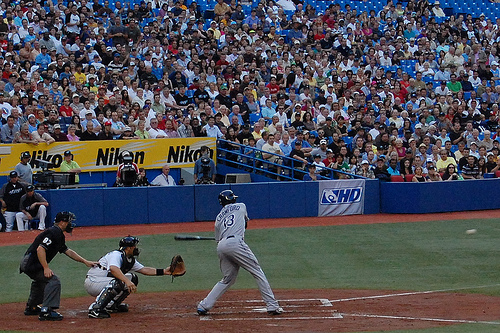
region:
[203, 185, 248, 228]
the head of a man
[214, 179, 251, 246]
the back of a man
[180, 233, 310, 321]
the legs of a man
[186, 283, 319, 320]
the feet of a man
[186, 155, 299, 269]
a man holding a bat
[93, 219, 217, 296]
a man wearing a baseball glove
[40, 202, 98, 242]
a man wearing a face mask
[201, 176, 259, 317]
a man wearing a uniform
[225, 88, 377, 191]
people in the stands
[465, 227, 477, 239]
a white baseball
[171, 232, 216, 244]
a long black baseball bat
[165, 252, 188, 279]
a large brown glove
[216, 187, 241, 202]
a black helmet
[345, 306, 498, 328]
a long white line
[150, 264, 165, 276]
a black wristband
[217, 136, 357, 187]
a long blue rail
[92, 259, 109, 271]
part of a man's black belt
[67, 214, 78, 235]
a black face mask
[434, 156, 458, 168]
a man's yellow shirt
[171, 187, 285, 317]
Baseball player playing baseball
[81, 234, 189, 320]
Catcher playing baseball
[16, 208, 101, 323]
Baseball referee playing baseball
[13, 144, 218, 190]
Camera men recording a baseball game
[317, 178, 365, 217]
Advertisement sign on a baseball field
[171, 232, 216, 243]
Black baseball bat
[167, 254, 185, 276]
Baseball catching mitt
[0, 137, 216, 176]
Yellow advertisement sign for Nikon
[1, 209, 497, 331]
Baseball playing field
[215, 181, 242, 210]
a man wearing a helmet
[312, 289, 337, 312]
a white line on the ground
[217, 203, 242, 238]
a number on the back of a shirt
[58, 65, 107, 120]
people watching a baseball game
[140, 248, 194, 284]
a man with a brown baseball glove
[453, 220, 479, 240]
a ball flying in the air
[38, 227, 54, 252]
numbers on the sleeve of the shirt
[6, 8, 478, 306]
Major league baseball game being played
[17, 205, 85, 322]
umpire in protective gear observing the game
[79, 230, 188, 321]
catcher with his arm extended preparing to catch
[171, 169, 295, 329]
batter in position to play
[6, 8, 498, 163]
large group of spectators in the stadium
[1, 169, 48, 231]
coaches observing from the side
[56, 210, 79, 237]
black face mask on the umpires face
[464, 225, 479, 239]
white baseball sailing through the air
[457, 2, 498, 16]
empty blue stadium seats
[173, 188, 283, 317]
baseball player ready to hit the ball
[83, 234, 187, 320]
baseball catcher waiting for the ball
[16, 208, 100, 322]
umpire watches pitch closely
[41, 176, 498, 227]
blue padding at the fences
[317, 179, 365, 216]
blue and white advertising on fence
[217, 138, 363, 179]
blue metal railing around where spectator's are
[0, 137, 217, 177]
yellow black and white Nikon advertisement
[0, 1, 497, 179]
spectators at the ball game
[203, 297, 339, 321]
home plate marked off in white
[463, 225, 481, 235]
ball moving along at the batter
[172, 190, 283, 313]
a baseball player at bat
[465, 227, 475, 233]
a white baseball in mid flight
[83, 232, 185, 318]
a baseball catcher crouching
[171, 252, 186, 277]
a brown leather glove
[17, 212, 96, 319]
a baseball umpire crouching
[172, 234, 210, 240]
a black baseball bat